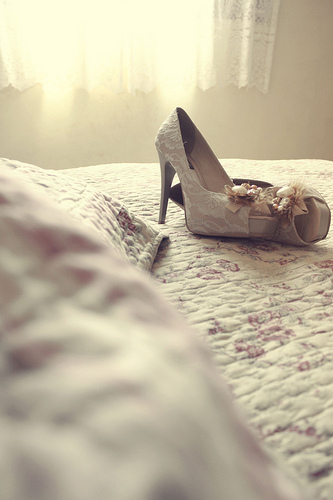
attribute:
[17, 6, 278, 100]
curtain — white, covering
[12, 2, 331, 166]
wall — cream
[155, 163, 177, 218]
heel — four inch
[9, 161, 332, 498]
blanket — blurred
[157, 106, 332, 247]
high heels — tipped, standing, decorative, high heels`, open toed, wedding, toe less